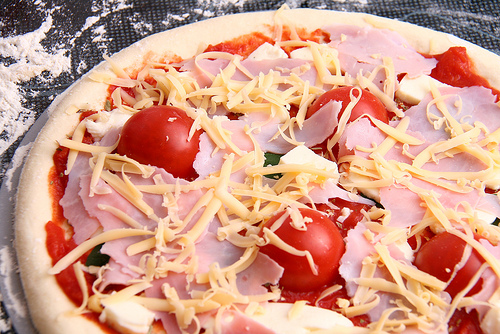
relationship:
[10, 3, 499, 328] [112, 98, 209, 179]
pizza has cherry tomato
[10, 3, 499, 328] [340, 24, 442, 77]
pizza has ham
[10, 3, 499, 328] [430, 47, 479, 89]
pizza has tomato sauce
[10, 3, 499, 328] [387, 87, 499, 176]
pizza has ham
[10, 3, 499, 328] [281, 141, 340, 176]
pizza has cheese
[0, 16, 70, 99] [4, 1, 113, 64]
flour on table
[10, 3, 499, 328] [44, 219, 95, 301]
pizza has sauce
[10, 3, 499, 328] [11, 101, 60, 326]
pizza has dough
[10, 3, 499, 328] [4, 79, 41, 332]
pizza on tray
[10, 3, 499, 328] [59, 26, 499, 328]
pizza has many toppings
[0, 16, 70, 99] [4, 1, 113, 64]
flour poured in table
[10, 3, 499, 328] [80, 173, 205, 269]
pizza has ham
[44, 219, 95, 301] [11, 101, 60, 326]
sauce on dough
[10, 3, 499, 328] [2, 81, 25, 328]
pizza on sheet